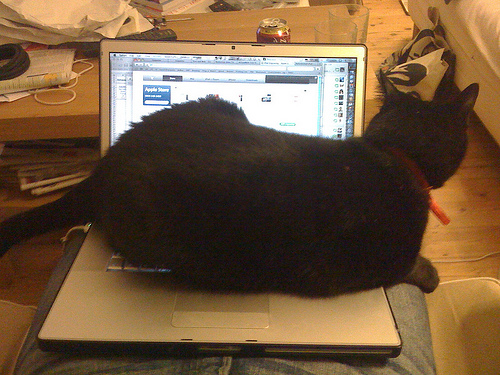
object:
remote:
[79, 24, 178, 56]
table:
[0, 3, 366, 147]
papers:
[29, 174, 102, 196]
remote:
[393, 0, 415, 17]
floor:
[354, 0, 500, 285]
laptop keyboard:
[103, 251, 180, 279]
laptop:
[34, 36, 409, 363]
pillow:
[373, 26, 463, 101]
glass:
[311, 19, 360, 48]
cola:
[254, 15, 294, 46]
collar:
[383, 142, 455, 228]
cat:
[0, 67, 479, 300]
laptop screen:
[107, 43, 364, 162]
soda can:
[254, 16, 292, 47]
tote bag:
[373, 22, 464, 116]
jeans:
[13, 229, 433, 374]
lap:
[27, 222, 439, 370]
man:
[11, 230, 439, 375]